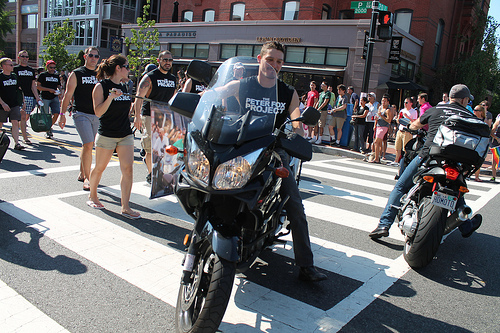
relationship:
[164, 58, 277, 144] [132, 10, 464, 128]
small window on building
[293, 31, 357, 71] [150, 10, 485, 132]
window on building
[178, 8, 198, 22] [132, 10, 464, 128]
window on building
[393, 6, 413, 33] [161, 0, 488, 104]
window on building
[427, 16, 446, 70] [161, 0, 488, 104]
small window on building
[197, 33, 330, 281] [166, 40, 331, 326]
man on motorcycle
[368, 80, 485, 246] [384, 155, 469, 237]
man wearing jeans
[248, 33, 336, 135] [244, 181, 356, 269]
man wearing jeans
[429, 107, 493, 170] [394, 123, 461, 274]
bag on back of motorcycle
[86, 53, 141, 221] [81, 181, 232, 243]
pedestrian wearing sandals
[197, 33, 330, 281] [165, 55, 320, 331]
man on motorcycle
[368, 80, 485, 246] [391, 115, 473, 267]
man on motorcycle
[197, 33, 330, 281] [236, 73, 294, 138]
man with shirt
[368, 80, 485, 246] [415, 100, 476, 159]
man with shirt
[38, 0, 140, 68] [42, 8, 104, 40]
building with windows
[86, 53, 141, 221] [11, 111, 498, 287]
pedestrian walking on street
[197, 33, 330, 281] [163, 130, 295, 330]
man on motorcycle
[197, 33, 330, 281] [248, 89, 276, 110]
man wearing shirt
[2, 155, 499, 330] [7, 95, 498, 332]
crosswalk on city street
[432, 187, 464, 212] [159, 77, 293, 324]
plate on motorcycle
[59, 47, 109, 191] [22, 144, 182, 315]
pedestrian on pavement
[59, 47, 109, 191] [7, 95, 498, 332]
pedestrian walking on city street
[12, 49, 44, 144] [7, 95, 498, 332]
person walking on city street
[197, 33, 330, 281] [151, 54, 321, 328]
man on motorcycle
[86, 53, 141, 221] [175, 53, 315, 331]
pedestrian on motorcycle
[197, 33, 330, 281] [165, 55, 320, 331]
man sitting on motorcycle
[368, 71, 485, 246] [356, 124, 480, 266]
man sitting on motorcycle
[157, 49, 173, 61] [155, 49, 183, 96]
hair on man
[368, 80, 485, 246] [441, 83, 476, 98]
man wearing hat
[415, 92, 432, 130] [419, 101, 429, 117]
man wearing shirt